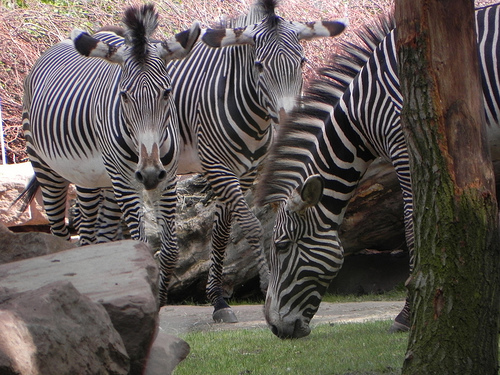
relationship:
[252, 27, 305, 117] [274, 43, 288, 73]
zebra's face has markings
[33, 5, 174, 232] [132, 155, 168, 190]
zebra has a nose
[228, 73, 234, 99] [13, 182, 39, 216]
hair on tail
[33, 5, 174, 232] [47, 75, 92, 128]
zebra covered in stripes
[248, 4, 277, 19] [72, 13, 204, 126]
hair on head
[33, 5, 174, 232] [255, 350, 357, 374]
zebra standing in grass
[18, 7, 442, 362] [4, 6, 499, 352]
zebras in picture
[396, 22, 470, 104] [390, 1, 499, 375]
tree has a tree trunk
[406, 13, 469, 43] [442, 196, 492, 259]
tree trunk has moss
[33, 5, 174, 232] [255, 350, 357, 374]
zebra eating grass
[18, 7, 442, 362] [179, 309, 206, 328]
park has stone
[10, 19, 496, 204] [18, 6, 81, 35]
park has forest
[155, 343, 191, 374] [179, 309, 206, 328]
area under stone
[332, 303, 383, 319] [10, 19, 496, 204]
ground in park